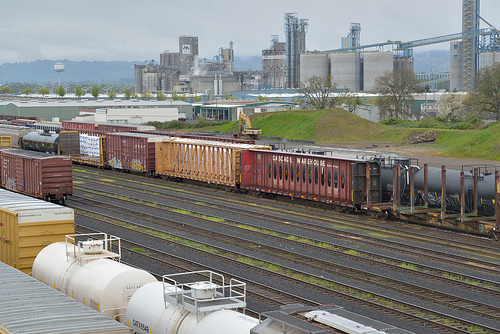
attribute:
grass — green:
[255, 110, 325, 139]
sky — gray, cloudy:
[3, 3, 497, 54]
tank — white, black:
[33, 231, 165, 313]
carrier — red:
[242, 145, 367, 212]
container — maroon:
[107, 128, 155, 173]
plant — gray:
[138, 11, 489, 106]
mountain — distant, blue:
[2, 58, 135, 86]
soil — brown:
[385, 142, 443, 157]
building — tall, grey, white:
[175, 33, 203, 90]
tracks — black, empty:
[101, 183, 250, 219]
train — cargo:
[9, 124, 499, 220]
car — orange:
[152, 140, 241, 184]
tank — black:
[18, 127, 70, 160]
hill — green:
[247, 106, 361, 151]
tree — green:
[156, 92, 170, 103]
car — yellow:
[3, 186, 79, 278]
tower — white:
[49, 59, 71, 98]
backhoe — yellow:
[237, 108, 266, 143]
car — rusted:
[364, 158, 499, 240]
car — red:
[64, 118, 147, 135]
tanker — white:
[127, 253, 266, 333]